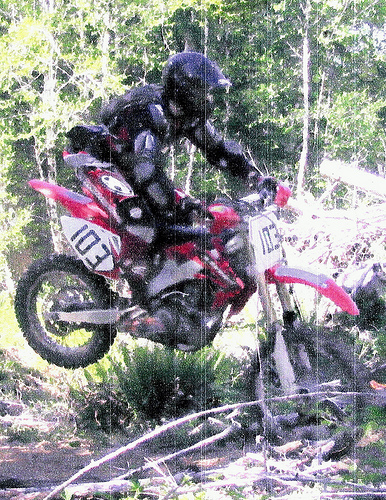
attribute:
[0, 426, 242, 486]
dirt — brown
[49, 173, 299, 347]
dirt bike — red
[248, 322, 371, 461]
wheel — silver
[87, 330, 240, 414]
plant — green, leafy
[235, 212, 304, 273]
numbers — black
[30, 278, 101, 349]
spokes — silver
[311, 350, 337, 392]
spokes — silver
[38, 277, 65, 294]
spokes — silver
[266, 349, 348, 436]
spokes — silver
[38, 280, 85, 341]
spokes — silver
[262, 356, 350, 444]
spokes — silver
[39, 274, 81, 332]
spokes — silver